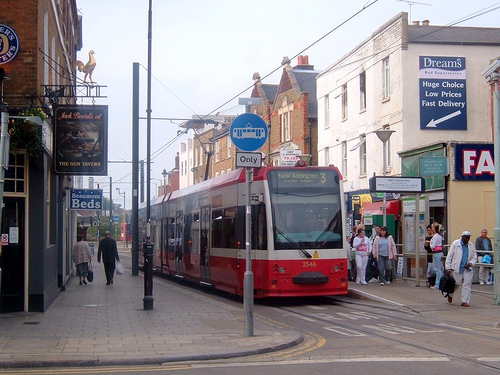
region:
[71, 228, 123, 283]
two people walking on the sidewalk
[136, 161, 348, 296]
trolley train on the street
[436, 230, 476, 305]
man walking in the sidewalk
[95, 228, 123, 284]
man holding a bag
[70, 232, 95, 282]
woman carrying a bag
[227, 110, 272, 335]
sign on top of post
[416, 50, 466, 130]
advertisement on wall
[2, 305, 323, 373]
yellow lines on the street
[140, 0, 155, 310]
metal post on the sidewalk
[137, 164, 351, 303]
white and red trolley train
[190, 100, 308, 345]
blue lamp post on street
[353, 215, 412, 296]
people walking on side walk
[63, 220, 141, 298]
people walking along side walk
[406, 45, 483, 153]
sign on wall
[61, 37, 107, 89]
gold chicken statue on sign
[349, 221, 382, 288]
lady wearing white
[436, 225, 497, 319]
man wearing white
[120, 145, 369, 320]
red and white tram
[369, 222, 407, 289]
lady wearing blue shirt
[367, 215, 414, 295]
lady wearing pink cardigan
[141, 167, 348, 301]
red and white trolly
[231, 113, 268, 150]
blue and white sign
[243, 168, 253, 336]
grey metal sign post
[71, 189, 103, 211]
blue and white sign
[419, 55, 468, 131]
blue and white sign on building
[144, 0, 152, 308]
black metal lamp post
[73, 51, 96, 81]
rooster figure on pole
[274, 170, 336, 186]
destination sign on trolly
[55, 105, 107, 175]
sign hanging on wall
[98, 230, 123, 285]
man carrying shopping bag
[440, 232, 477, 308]
Man walking on the sidewalk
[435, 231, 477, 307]
Man carrying a black suitcase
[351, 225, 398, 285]
Two women walking on the sidewalk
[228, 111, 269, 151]
Circular blue sign with a white bus symbol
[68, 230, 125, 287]
Two dressed up people walking on the sidewalk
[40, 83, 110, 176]
Rectangular black sign hanging from metal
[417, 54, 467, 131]
Large rectangle blue and white sign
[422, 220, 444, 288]
Two women standing with each other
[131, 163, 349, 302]
Large white and red transit bus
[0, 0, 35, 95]
Brick wall with a circular sign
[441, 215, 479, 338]
Person walking on pavement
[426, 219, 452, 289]
Person walking on pavement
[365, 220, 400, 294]
Person walking on pavement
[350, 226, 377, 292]
Person walking on pavement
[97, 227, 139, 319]
Person walking on pavement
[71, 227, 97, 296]
Person walking on pavement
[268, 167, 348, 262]
Large window on a bus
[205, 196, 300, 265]
Large window on a bus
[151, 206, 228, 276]
Large window on a bus